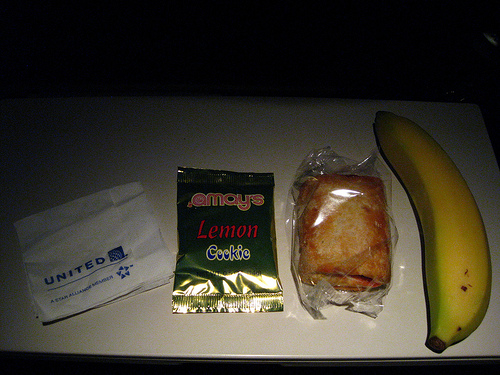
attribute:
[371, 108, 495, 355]
banana — yellow, brown, unopen, unpeeled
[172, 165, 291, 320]
cookie package — wrapped, gold, golden, gleaming, dessert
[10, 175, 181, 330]
napkin — white, blue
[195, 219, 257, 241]
letters — red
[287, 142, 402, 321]
plastic — clear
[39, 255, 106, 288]
letters — blue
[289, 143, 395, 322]
dessert — wrapped, red inside, small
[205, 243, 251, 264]
letters — blue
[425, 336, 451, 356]
stem — brown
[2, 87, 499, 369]
table — white, small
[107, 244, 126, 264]
logo — blue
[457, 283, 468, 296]
spot — brown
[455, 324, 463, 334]
spot — brown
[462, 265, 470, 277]
spot — brown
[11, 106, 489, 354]
food — uneaten, untouched, lined up, line up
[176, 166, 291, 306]
cookies — lemon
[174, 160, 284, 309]
container — shiny